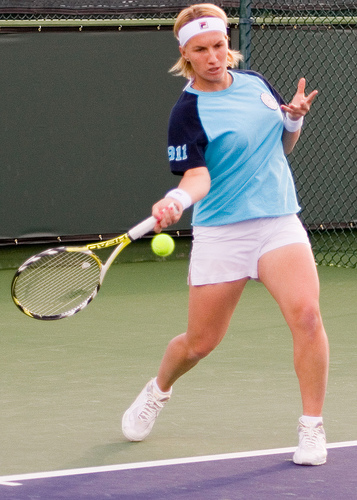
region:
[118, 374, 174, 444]
White shoe of tennis player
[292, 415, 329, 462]
White shoe of tennis player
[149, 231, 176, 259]
Yellow/green flying tennis ball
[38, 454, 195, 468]
Part of white sideline stripe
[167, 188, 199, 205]
White wristband of tennis player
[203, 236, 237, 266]
Part of white tennis player shorts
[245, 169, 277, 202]
Part of blue tennis player shirt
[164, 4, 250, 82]
Head of tennis player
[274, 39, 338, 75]
Chain link tennis area fence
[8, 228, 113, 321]
Part of tennis player racket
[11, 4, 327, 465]
woman about to hit tennis ball with racquet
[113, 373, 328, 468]
women's white sneakers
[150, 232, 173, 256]
tennis ball in mid air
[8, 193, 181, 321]
black, yellow, and white tennis racket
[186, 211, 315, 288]
white tennis skirt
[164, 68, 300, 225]
light blue and navy blue tennis top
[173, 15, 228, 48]
white headband with logo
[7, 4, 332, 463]
woman with short blonde hair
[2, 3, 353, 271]
fence around tennis court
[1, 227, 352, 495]
purple, green, and white floor of tennis court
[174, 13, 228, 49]
White headband worn by player.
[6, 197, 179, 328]
White, black and yellow tennis racket.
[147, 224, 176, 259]
Tennis ball in mid air.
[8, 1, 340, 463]
Woman playing tennis on court.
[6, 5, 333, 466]
Tennis player swinging racket.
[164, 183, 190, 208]
White wrist band on right wrist.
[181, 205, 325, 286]
White shorts worn by player.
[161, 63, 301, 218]
Blue two-toned shirt worn by player.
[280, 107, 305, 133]
White wrist band on left wrist.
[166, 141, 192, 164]
'911' in blue on shirt.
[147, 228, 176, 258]
bright green ball in motion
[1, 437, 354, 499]
purple tennis court outlined in white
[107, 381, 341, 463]
white tennis shoes and socks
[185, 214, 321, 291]
white shorts with side slit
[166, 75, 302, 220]
two toned blue t-shirt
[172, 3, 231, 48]
white sweat band on blond hair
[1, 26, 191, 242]
grey tarp attached to fence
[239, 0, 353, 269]
high chain link fence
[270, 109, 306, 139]
white wrist band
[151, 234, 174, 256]
A yellow tennis ball in the air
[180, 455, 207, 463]
The white baseline on a tennis court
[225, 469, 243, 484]
The shadow of a tennis player on the court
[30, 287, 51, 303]
White string on a tennis racket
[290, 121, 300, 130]
A white cloth wristband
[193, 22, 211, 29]
The Fila logo on a tennis headband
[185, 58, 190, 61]
A woman's pierced ear with an earring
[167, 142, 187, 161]
Numbers on a shirt sleeve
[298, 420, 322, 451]
White laces on a woman's white tennis shoe